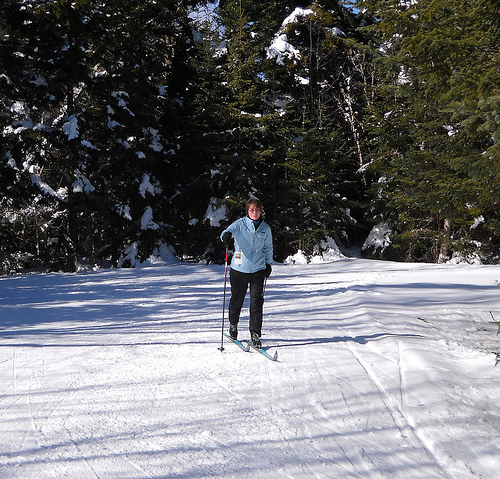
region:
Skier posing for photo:
[205, 193, 287, 367]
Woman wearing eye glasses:
[241, 196, 263, 221]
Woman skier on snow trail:
[209, 197, 282, 367]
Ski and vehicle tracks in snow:
[326, 334, 486, 475]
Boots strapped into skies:
[221, 328, 283, 363]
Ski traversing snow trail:
[218, 320, 280, 364]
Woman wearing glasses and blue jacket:
[216, 193, 280, 275]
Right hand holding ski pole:
[212, 230, 237, 353]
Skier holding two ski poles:
[213, 228, 273, 351]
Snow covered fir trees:
[1, 4, 498, 265]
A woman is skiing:
[203, 192, 300, 374]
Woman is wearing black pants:
[221, 264, 279, 351]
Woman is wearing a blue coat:
[213, 209, 279, 282]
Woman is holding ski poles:
[213, 237, 280, 363]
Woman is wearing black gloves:
[216, 224, 281, 281]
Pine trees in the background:
[0, 3, 496, 271]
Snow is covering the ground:
[0, 261, 496, 476]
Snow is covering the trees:
[2, 0, 497, 266]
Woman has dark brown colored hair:
[235, 193, 266, 224]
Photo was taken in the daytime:
[2, 0, 492, 475]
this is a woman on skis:
[188, 170, 339, 395]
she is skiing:
[196, 171, 341, 381]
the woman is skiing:
[201, 186, 316, 376]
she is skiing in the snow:
[197, 169, 331, 386]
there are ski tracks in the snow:
[8, 342, 450, 477]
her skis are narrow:
[205, 320, 306, 370]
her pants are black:
[216, 257, 276, 341]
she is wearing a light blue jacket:
[201, 173, 325, 405]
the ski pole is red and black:
[208, 234, 239, 356]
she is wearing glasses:
[239, 187, 265, 226]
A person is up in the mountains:
[48, 106, 449, 432]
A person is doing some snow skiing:
[36, 85, 476, 460]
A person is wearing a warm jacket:
[35, 53, 477, 434]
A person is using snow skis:
[30, 100, 471, 445]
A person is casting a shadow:
[46, 133, 447, 433]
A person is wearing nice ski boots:
[50, 86, 470, 451]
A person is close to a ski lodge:
[41, 80, 474, 441]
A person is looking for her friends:
[60, 81, 485, 427]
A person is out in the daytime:
[47, 101, 437, 433]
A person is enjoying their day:
[107, 129, 404, 444]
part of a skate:
[236, 342, 243, 354]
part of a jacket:
[228, 258, 250, 306]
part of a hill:
[353, 315, 366, 360]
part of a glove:
[263, 257, 275, 284]